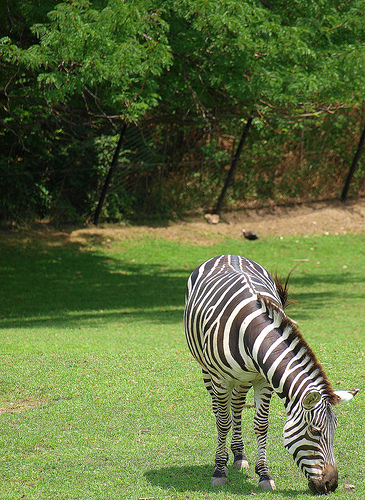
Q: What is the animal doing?
A: Eating.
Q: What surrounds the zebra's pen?
A: Fence and trees.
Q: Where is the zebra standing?
A: In the grass.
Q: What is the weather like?
A: Sunny.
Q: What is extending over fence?
A: Trees.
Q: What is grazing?
A: Zebra.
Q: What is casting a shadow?
A: Trees.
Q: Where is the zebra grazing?
A: On the grass.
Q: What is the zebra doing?
A: Eating.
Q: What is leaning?
A: Metal chain link fence.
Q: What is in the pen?
A: Rocks and dirt.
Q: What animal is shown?
A: Zebra.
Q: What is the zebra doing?
A: Grazing.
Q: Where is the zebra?
A: Field.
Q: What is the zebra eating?
A: Grass.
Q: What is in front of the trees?
A: Fence.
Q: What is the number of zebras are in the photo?
A: 1.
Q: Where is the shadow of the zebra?
A: Under zeba.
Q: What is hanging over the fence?
A: Trees.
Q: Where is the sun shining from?
A: Right.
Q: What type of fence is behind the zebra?
A: Chain linked.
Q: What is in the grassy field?
A: A zebra.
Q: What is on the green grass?
A: A zebra.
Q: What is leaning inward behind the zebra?
A: The fence.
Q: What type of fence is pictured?
A: A black metal fence.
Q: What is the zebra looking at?
A: The grass.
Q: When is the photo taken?
A: Day time.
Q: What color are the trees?
A: Green.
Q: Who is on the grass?
A: The zebra.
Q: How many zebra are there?
A: One.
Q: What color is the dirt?
A: Brown.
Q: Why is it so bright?
A: Sunny.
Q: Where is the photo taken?
A: In a zoo.